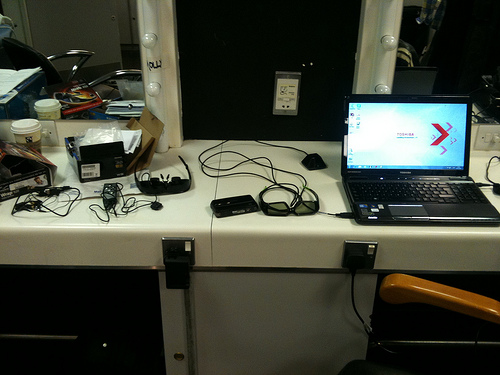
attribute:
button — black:
[357, 186, 359, 191]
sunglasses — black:
[256, 182, 321, 219]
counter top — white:
[54, 139, 349, 272]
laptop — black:
[333, 85, 498, 230]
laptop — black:
[341, 93, 498, 226]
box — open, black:
[58, 123, 153, 178]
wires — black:
[201, 154, 296, 217]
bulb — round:
[133, 27, 165, 108]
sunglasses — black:
[127, 154, 192, 196]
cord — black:
[196, 126, 335, 217]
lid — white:
[8, 116, 39, 133]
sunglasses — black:
[257, 186, 319, 216]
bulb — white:
[135, 27, 161, 51]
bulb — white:
[140, 75, 165, 102]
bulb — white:
[371, 29, 399, 54]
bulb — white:
[368, 75, 391, 93]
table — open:
[34, 80, 477, 310]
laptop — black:
[311, 96, 482, 233]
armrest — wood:
[380, 263, 489, 340]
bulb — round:
[147, 82, 162, 95]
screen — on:
[345, 104, 470, 168]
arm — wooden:
[378, 269, 497, 321]